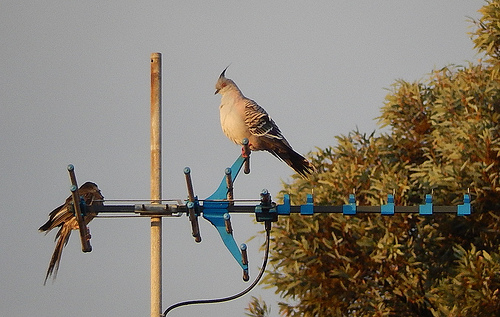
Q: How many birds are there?
A: 2.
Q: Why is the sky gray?
A: It is cloudy.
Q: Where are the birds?
A: On the pole.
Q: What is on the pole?
A: The birds.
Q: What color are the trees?
A: Green.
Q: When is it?
A: Day time.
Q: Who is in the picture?
A: The birds.